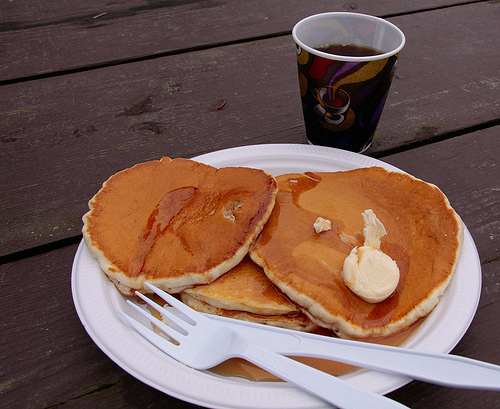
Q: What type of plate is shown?
A: Paper.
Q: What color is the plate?
A: White.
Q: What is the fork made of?
A: Plastic.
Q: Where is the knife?
A: Under the fork.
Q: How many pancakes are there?
A: Four.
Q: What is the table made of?
A: Wood.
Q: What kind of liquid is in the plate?
A: Syrup.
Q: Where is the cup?
A: Table.